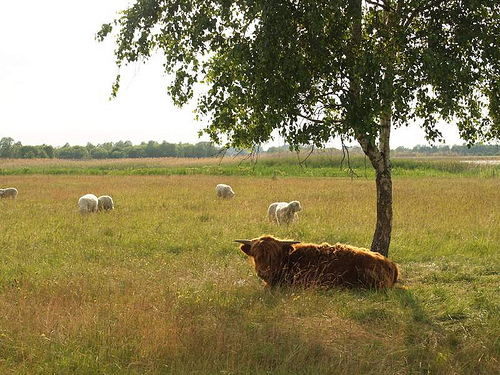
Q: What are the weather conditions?
A: It is clear.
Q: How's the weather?
A: It is clear.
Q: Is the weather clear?
A: Yes, it is clear.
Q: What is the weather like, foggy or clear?
A: It is clear.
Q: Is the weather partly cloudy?
A: No, it is clear.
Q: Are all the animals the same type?
A: No, there are both sheep and bulls.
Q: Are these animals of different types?
A: Yes, they are sheep and bulls.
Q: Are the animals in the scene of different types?
A: Yes, they are sheep and bulls.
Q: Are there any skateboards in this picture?
A: No, there are no skateboards.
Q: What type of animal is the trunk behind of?
A: The trunk is behind the bull.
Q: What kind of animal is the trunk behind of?
A: The trunk is behind the bull.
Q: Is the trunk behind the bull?
A: Yes, the trunk is behind the bull.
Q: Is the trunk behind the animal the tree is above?
A: Yes, the trunk is behind the bull.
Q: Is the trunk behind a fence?
A: No, the trunk is behind the bull.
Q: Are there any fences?
A: No, there are no fences.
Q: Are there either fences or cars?
A: No, there are no fences or cars.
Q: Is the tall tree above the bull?
A: Yes, the tree is above the bull.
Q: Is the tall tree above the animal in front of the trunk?
A: Yes, the tree is above the bull.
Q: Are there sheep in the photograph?
A: Yes, there is a sheep.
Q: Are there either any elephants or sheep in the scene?
A: Yes, there is a sheep.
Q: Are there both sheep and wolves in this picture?
A: No, there is a sheep but no wolves.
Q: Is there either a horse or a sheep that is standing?
A: Yes, the sheep is standing.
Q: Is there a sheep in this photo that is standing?
A: Yes, there is a sheep that is standing.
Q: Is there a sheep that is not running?
A: Yes, there is a sheep that is standing.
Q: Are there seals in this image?
A: No, there are no seals.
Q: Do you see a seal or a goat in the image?
A: No, there are no seals or goats.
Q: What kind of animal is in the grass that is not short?
A: The animal is a sheep.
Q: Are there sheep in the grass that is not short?
A: Yes, there is a sheep in the grass.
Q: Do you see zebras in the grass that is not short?
A: No, there is a sheep in the grass.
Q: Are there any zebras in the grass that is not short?
A: No, there is a sheep in the grass.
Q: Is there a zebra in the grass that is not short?
A: No, there is a sheep in the grass.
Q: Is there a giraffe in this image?
A: No, there are no giraffes.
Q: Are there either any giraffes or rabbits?
A: No, there are no giraffes or rabbits.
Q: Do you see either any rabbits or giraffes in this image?
A: No, there are no giraffes or rabbits.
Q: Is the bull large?
A: Yes, the bull is large.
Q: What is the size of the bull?
A: The bull is large.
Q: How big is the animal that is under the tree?
A: The bull is large.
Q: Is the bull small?
A: No, the bull is large.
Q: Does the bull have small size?
A: No, the bull is large.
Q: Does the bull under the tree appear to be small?
A: No, the bull is large.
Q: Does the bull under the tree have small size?
A: No, the bull is large.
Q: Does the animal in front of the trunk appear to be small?
A: No, the bull is large.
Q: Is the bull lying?
A: Yes, the bull is lying.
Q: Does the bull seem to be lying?
A: Yes, the bull is lying.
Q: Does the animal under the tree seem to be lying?
A: Yes, the bull is lying.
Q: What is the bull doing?
A: The bull is lying.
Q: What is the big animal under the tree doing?
A: The bull is lying.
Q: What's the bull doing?
A: The bull is lying.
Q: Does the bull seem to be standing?
A: No, the bull is lying.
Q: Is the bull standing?
A: No, the bull is lying.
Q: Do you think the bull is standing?
A: No, the bull is lying.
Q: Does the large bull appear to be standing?
A: No, the bull is lying.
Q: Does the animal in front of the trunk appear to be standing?
A: No, the bull is lying.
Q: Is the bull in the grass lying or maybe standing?
A: The bull is lying.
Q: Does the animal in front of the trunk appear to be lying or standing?
A: The bull is lying.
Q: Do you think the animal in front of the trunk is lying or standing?
A: The bull is lying.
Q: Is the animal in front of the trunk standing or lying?
A: The bull is lying.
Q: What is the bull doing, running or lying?
A: The bull is lying.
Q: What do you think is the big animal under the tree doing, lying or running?
A: The bull is lying.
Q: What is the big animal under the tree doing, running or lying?
A: The bull is lying.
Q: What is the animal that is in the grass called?
A: The animal is a bull.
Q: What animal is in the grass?
A: The animal is a bull.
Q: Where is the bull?
A: The bull is in the grass.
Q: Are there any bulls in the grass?
A: Yes, there is a bull in the grass.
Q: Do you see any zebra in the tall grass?
A: No, there is a bull in the grass.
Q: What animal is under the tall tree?
A: The bull is under the tree.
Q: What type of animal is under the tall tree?
A: The animal is a bull.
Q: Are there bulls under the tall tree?
A: Yes, there is a bull under the tree.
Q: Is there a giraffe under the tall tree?
A: No, there is a bull under the tree.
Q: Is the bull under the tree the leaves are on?
A: Yes, the bull is under the tree.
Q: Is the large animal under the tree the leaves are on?
A: Yes, the bull is under the tree.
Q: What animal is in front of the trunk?
A: The animal is a bull.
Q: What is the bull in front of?
A: The bull is in front of the trunk.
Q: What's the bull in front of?
A: The bull is in front of the trunk.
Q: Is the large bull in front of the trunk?
A: Yes, the bull is in front of the trunk.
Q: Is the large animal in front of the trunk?
A: Yes, the bull is in front of the trunk.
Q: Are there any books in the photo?
A: No, there are no books.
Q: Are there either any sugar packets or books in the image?
A: No, there are no books or sugar packets.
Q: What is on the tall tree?
A: The leaves are on the tree.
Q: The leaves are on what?
A: The leaves are on the tree.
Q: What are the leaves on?
A: The leaves are on the tree.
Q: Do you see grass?
A: Yes, there is grass.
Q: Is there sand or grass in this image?
A: Yes, there is grass.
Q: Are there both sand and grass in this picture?
A: No, there is grass but no sand.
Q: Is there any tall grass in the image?
A: Yes, there is tall grass.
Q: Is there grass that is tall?
A: Yes, there is grass that is tall.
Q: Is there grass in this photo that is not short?
A: Yes, there is tall grass.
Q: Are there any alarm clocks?
A: No, there are no alarm clocks.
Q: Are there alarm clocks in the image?
A: No, there are no alarm clocks.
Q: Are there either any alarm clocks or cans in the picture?
A: No, there are no alarm clocks or cans.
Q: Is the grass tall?
A: Yes, the grass is tall.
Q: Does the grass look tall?
A: Yes, the grass is tall.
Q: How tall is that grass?
A: The grass is tall.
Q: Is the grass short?
A: No, the grass is tall.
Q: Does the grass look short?
A: No, the grass is tall.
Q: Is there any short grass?
A: No, there is grass but it is tall.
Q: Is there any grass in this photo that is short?
A: No, there is grass but it is tall.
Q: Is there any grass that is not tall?
A: No, there is grass but it is tall.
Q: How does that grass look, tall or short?
A: The grass is tall.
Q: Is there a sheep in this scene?
A: Yes, there is a sheep.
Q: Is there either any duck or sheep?
A: Yes, there is a sheep.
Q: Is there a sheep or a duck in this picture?
A: Yes, there is a sheep.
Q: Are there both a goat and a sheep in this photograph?
A: No, there is a sheep but no goats.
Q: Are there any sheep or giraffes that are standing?
A: Yes, the sheep is standing.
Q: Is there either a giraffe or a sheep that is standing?
A: Yes, the sheep is standing.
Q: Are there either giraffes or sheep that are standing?
A: Yes, the sheep is standing.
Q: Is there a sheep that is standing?
A: Yes, there is a sheep that is standing.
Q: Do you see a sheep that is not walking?
A: Yes, there is a sheep that is standing .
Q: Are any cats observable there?
A: No, there are no cats.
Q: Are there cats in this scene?
A: No, there are no cats.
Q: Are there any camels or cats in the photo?
A: No, there are no cats or camels.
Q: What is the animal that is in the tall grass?
A: The animal is a sheep.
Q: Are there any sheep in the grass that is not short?
A: Yes, there is a sheep in the grass.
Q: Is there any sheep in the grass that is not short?
A: Yes, there is a sheep in the grass.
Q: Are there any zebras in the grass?
A: No, there is a sheep in the grass.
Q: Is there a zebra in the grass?
A: No, there is a sheep in the grass.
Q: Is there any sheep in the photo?
A: Yes, there is a sheep.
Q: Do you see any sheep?
A: Yes, there is a sheep.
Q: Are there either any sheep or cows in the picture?
A: Yes, there is a sheep.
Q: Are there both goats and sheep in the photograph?
A: No, there is a sheep but no goats.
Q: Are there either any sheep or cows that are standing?
A: Yes, the sheep is standing.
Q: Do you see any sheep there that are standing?
A: Yes, there is a sheep that is standing.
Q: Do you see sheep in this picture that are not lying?
A: Yes, there is a sheep that is standing .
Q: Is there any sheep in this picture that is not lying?
A: Yes, there is a sheep that is standing.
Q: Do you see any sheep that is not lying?
A: Yes, there is a sheep that is standing .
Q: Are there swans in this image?
A: No, there are no swans.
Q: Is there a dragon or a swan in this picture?
A: No, there are no swans or dragons.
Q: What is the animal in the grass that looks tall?
A: The animal is a sheep.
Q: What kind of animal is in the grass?
A: The animal is a sheep.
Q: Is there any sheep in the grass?
A: Yes, there is a sheep in the grass.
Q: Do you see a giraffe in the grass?
A: No, there is a sheep in the grass.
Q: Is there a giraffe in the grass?
A: No, there is a sheep in the grass.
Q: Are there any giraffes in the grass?
A: No, there is a sheep in the grass.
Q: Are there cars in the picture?
A: No, there are no cars.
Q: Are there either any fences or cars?
A: No, there are no cars or fences.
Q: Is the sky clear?
A: Yes, the sky is clear.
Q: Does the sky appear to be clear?
A: Yes, the sky is clear.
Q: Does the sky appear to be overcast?
A: No, the sky is clear.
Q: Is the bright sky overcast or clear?
A: The sky is clear.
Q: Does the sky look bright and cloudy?
A: No, the sky is bright but clear.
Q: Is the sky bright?
A: Yes, the sky is bright.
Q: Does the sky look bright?
A: Yes, the sky is bright.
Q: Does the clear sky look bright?
A: Yes, the sky is bright.